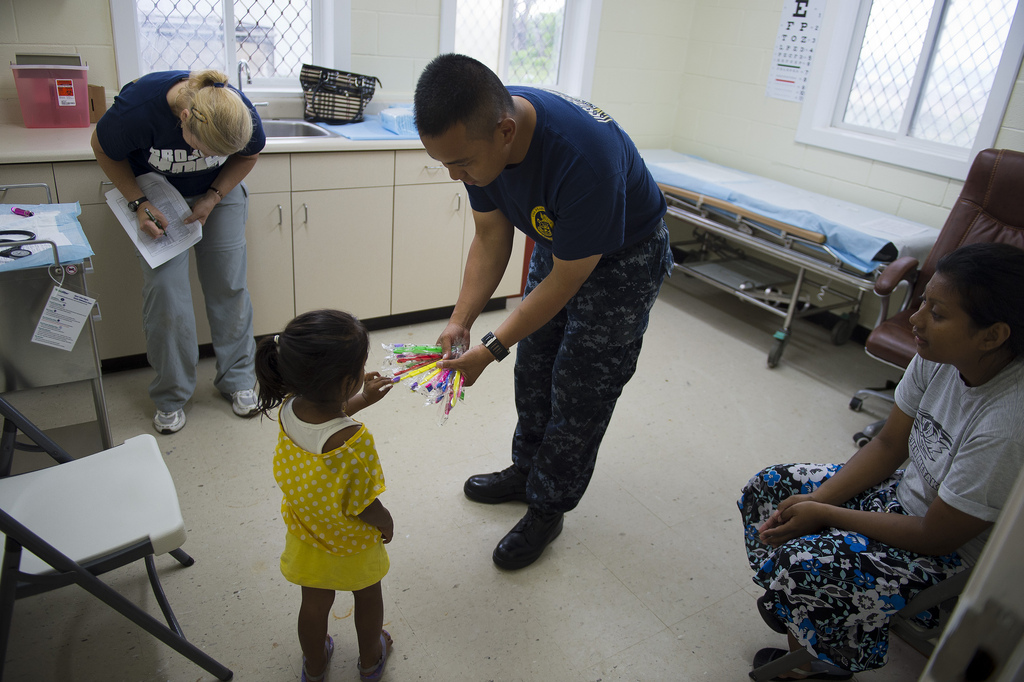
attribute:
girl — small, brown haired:
[227, 290, 424, 604]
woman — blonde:
[97, 68, 333, 252]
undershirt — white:
[266, 398, 359, 465]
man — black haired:
[354, 18, 676, 280]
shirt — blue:
[471, 95, 638, 309]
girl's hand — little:
[350, 368, 403, 420]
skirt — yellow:
[261, 510, 393, 591]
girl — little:
[233, 290, 367, 470]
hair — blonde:
[172, 61, 270, 167]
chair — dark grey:
[8, 387, 225, 677]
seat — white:
[4, 437, 225, 576]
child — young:
[209, 279, 426, 677]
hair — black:
[233, 303, 398, 431]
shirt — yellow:
[248, 420, 396, 604]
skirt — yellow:
[283, 497, 381, 591]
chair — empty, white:
[0, 381, 268, 675]